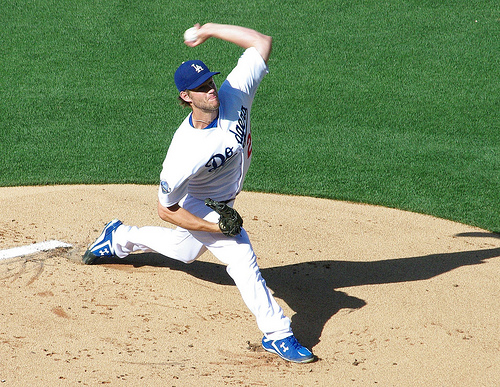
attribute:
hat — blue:
[170, 52, 214, 89]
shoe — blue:
[254, 335, 313, 372]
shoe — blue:
[84, 206, 137, 277]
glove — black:
[214, 188, 253, 255]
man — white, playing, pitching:
[134, 29, 372, 309]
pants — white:
[132, 214, 295, 312]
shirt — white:
[170, 126, 260, 206]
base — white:
[8, 236, 71, 270]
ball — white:
[178, 22, 210, 47]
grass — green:
[10, 8, 436, 177]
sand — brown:
[13, 194, 367, 373]